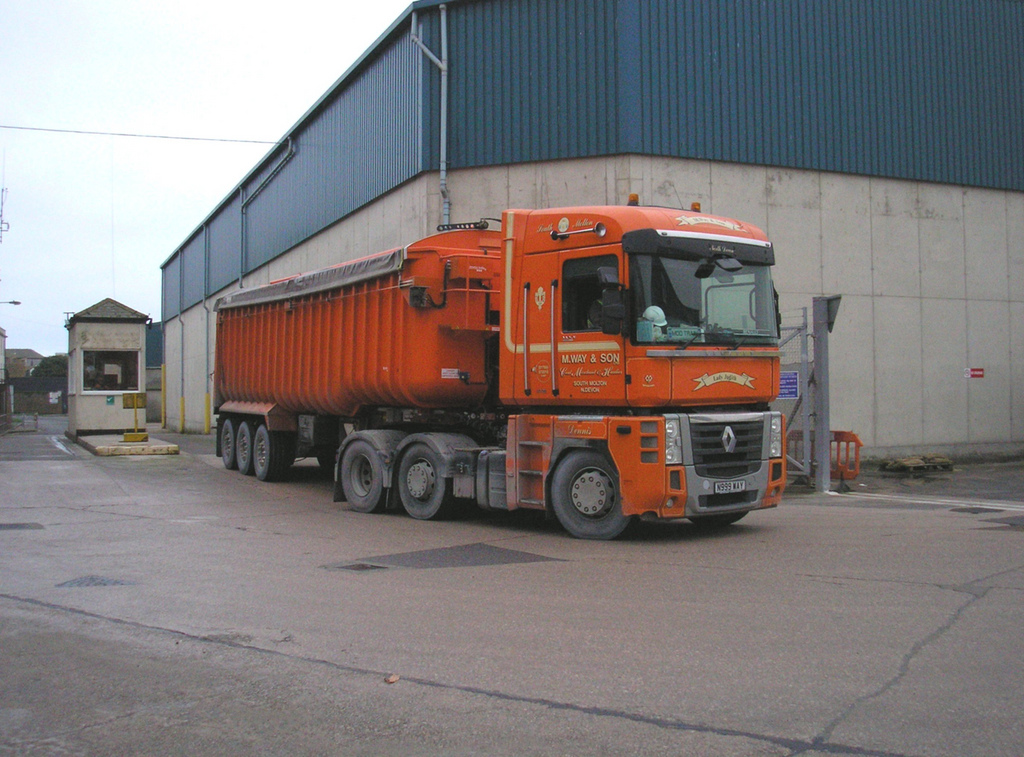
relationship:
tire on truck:
[371, 420, 519, 563] [226, 184, 907, 636]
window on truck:
[619, 228, 780, 347] [203, 187, 795, 542]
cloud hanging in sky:
[3, 3, 408, 323] [3, 5, 405, 358]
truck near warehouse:
[203, 187, 795, 542] [155, 0, 1018, 472]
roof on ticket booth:
[60, 289, 158, 333] [62, 297, 154, 441]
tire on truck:
[541, 440, 642, 542] [203, 187, 795, 542]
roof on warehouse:
[158, 5, 1020, 316] [155, 0, 1018, 472]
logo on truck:
[715, 421, 741, 458] [203, 187, 795, 542]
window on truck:
[629, 254, 780, 347] [203, 187, 795, 542]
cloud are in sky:
[0, 0, 408, 321] [17, 11, 252, 189]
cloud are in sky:
[0, 0, 408, 321] [12, 54, 159, 283]